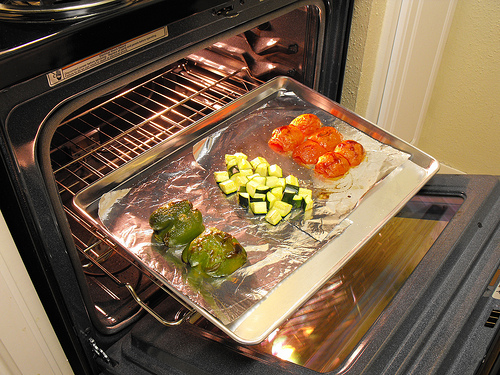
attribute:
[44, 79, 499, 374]
oven — open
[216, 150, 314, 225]
vegetables — green, yellow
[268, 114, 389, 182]
food — red, brown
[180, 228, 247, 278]
green pepper — grilled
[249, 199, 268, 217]
slice — gogget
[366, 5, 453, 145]
wall frame — white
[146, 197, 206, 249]
peppers — cooked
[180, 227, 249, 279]
peppers — cooked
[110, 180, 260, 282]
peppers — green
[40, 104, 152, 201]
rack — metal 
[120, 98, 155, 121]
rack — metal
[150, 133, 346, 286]
tray — silvery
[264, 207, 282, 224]
gogget — slice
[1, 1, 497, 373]
oven — open, black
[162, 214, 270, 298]
pepper — green, cooked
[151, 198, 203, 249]
pepper — green, grilled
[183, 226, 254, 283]
pepper — grilled, green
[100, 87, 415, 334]
paper — white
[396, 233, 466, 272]
door — oven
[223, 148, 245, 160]
gogget — slice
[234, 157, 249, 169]
gogget — slice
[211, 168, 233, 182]
gogget — slice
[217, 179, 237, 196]
gogget — slice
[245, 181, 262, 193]
gogget — slice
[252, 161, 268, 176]
gogget — slice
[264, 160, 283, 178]
gogget — slice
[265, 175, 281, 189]
gogget — slice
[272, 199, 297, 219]
gogget — slice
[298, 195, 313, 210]
gogget — slice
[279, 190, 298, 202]
gogget — slice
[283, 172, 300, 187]
gogget — slice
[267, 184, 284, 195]
gogget — slice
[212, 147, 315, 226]
cucumber — in small pieces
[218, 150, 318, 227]
zucchini — chopped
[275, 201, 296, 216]
slice — gogget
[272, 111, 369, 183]
tomato — grilled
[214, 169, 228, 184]
slice —  of gogget 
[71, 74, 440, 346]
tray — silver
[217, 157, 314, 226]
cucumber — green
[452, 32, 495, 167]
wall — dull-yellow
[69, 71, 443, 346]
pan — metal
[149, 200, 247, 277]
fruits — baked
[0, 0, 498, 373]
stove — top, range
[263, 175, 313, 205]
gogget — slice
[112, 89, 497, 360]
door — opened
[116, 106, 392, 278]
covering — aluminum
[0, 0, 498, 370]
window — glass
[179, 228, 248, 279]
fruit — green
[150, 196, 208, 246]
fruit — green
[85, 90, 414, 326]
soilpaper — silver